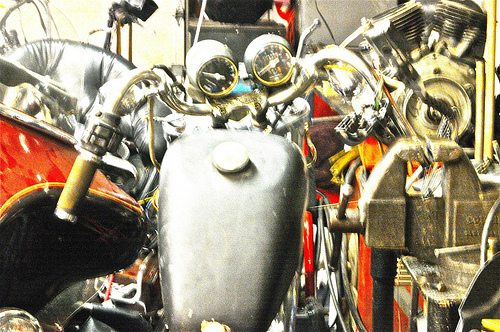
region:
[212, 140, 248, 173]
The metallic fuel cap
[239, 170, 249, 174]
Shadow cast by the fuel cap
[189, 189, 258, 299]
The metallic fuel tank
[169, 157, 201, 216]
Fuel tank reflecting light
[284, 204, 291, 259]
Shadow cast by fuel tank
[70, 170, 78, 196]
The left handle bar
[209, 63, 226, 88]
The gauge of a motorcycle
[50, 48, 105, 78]
The back rest of a seat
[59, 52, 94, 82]
The seat reflecting light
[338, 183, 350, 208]
The clamping handle of a vice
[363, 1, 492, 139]
an engine on a table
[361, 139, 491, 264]
A set of clamps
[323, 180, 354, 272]
the turning handle of the clamp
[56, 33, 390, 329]
The front of a motorcycle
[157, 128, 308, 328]
the gas tank of a motorcycle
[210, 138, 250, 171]
the cap of a gas tank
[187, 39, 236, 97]
A gauge on the front of the motorcycle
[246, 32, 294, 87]
A gauge on the front of the motorcycle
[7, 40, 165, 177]
A large black seat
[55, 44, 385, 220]
a pair of motorcycle handlebars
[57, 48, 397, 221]
Handlebars on the motorcycle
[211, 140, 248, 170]
The gas tank for the motorcycle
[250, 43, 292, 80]
The speedometer for the motorcycle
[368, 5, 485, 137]
An engine block by the motorcycle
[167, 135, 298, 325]
A gas tank on the motorcycle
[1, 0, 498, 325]
Motorcycle parts in the room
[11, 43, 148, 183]
A couch in the room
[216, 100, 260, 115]
Screws on the motorcycle handlebars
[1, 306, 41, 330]
A headlight on a motorcycle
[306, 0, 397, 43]
The room has a white wall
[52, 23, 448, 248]
handle bars of a motorcycle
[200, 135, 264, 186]
cap to a motorcycle gas tank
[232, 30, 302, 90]
a bike's spedometer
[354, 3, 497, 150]
a motor/engine parts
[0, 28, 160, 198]
leather of a possible motorcycle side car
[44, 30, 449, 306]
a bike in a shop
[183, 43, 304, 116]
dials/guages of a motorcycle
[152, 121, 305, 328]
fuel tank on a bike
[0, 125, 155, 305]
red fiberglass body of a motorcycle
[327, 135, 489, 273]
a metal vice in a workshop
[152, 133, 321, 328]
Black metal motorcycle fuel tank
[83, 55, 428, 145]
Chrome motorcycle handle bars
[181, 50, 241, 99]
Small round gauge on handlebars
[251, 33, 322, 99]
Small round gauge on handlebars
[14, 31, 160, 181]
Black leather vehicle seat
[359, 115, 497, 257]
Metal bench vise on right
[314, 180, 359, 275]
Turning handle to bench vice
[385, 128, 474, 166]
Metal teeth of bench vise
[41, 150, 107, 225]
Yellow handle on motorcycle handlebar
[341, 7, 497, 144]
Engine block on right